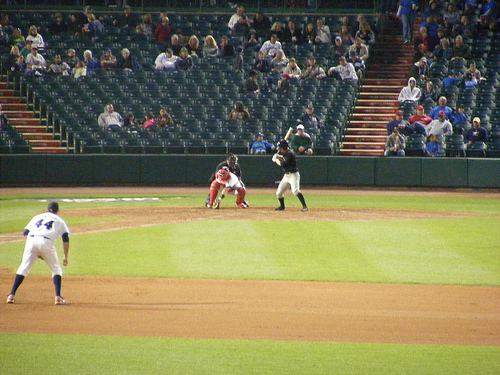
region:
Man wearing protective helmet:
[274, 136, 293, 154]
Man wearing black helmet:
[271, 135, 295, 159]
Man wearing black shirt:
[266, 147, 305, 171]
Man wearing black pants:
[274, 167, 310, 205]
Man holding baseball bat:
[261, 119, 302, 166]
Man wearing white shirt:
[14, 208, 85, 242]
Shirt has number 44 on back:
[25, 209, 68, 241]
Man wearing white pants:
[6, 231, 81, 286]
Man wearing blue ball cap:
[41, 195, 71, 220]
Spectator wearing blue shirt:
[247, 129, 277, 159]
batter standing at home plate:
[268, 128, 311, 213]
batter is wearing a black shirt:
[276, 151, 297, 173]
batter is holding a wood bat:
[275, 126, 295, 156]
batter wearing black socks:
[297, 192, 307, 207]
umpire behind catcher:
[208, 154, 241, 181]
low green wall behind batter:
[4, 153, 498, 190]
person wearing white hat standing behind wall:
[288, 124, 312, 154]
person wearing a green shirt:
[290, 132, 309, 153]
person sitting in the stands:
[96, 102, 121, 127]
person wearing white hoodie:
[397, 77, 422, 100]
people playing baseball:
[128, 97, 473, 296]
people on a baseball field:
[173, 114, 343, 239]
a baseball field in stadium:
[41, 184, 380, 374]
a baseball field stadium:
[21, 13, 448, 373]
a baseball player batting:
[244, 114, 356, 224]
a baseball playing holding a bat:
[248, 92, 333, 225]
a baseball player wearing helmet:
[269, 110, 321, 214]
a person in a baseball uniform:
[10, 175, 92, 326]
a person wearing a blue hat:
[10, 197, 122, 372]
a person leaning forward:
[0, 192, 115, 327]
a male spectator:
[100, 98, 128, 128]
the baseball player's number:
[32, 215, 52, 230]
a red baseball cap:
[415, 102, 423, 107]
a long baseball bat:
[278, 122, 294, 157]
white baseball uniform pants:
[275, 169, 303, 198]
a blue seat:
[186, 135, 203, 151]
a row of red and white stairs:
[0, 76, 65, 147]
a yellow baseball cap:
[470, 115, 481, 121]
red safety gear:
[237, 188, 245, 203]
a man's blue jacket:
[427, 103, 451, 116]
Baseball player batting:
[270, 136, 308, 211]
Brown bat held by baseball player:
[281, 123, 292, 144]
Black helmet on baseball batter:
[272, 135, 290, 155]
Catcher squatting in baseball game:
[201, 165, 249, 211]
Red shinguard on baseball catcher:
[205, 175, 220, 205]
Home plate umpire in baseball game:
[212, 151, 244, 181]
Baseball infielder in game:
[5, 200, 71, 305]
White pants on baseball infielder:
[15, 236, 61, 276]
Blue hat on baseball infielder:
[42, 196, 63, 211]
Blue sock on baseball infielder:
[50, 272, 63, 298]